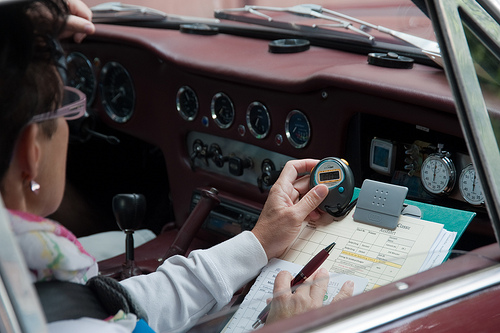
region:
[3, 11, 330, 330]
A passenger in a vehicle.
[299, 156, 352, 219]
A grey stopwatch.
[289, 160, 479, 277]
A green and grey clipboard.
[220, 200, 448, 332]
White papers on a clipboard.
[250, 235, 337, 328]
A red pen with a red grip.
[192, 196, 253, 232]
A vehicle radio.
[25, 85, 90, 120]
A pair of light pink framed glasses.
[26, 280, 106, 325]
Part of a grey seat belt.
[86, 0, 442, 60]
Silver windshield wiper blades.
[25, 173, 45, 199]
An earring.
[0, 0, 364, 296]
woman holding stopwatch and pen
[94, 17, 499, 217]
dark red dashboard with gauges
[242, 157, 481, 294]
teal clipboard with papers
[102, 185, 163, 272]
gear shifter with black top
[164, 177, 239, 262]
red handled parking brake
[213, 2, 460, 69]
chrome windshield wiper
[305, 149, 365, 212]
yellow teal and grey stopwatch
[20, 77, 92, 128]
light pink eyeglasses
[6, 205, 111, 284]
white, pink and yellow scarf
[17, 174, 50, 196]
small shiny silver earring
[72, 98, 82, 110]
WOMAN IS WEARING EYE GLASSES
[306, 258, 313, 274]
WRITTING PEN IS RED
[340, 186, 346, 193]
BLUE SMALL BUTTON ON THE CLOCK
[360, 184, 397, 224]
GREY CLIP IS ATTACHED TO THE TOP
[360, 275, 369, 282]
GLASS WINDOW IS ROLLED DOWN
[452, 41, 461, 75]
SILVER CROME AROUND THE EDGE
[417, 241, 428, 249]
PAPER IS WHITE ON THE BOARD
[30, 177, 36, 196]
LADY IS WEARNG A EARRING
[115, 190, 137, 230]
LEATHER RUBBER BALL AROUND THE GEARS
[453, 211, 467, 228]
THE BOARD IS BLUE THE WOMAN HOLDING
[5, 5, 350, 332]
an old woman wearing glasses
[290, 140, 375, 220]
a gray stopwatch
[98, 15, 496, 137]
a red dashboard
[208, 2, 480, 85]
a gray window washer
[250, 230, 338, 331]
a red ballpoint pen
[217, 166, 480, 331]
a green clipboard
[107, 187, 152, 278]
a black shift stick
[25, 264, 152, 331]
a gray seat belt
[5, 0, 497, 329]
a scene happening during the day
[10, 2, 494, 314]
a scene inside a car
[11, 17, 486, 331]
lady in passenger seat of car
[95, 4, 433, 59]
windshield wipers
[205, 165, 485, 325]
teal clipboard holding documents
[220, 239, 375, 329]
hand holding burgandy pen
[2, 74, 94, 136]
lady wearing transclucent pink glasses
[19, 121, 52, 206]
silver earring in right ear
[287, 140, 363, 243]
hand holding a pedometer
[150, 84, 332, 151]
four round gauges in dashboard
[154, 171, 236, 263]
emergency brake engaged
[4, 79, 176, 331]
lady wearing a seatbelt